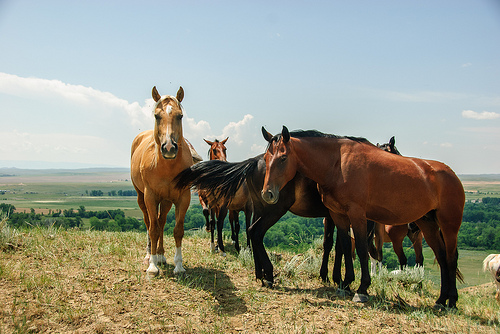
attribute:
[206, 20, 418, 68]
sky — light blue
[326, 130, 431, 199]
horse — horse's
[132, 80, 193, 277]
horse — light brown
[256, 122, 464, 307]
horse — brown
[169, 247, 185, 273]
sock — white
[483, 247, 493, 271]
tail — white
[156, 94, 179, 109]
forelock — blond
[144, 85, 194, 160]
head — horse's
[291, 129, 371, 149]
mane — black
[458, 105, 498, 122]
cloud — small, white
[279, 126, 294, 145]
ear — black